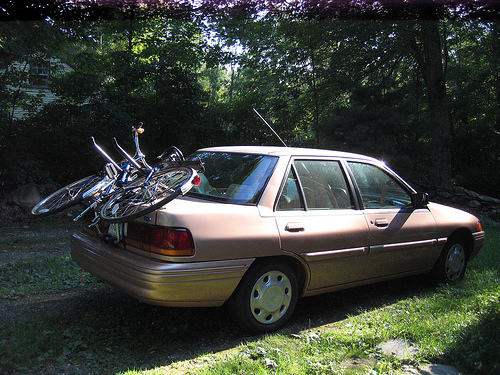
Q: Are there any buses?
A: No, there are no buses.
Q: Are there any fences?
A: No, there are no fences.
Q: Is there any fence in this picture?
A: No, there are no fences.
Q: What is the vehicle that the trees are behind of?
A: The vehicle is a car.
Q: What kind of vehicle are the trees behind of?
A: The trees are behind the car.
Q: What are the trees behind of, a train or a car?
A: The trees are behind a car.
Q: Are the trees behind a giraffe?
A: No, the trees are behind the car.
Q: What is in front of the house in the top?
A: The trees are in front of the house.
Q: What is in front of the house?
A: The trees are in front of the house.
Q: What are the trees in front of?
A: The trees are in front of the house.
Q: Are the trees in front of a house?
A: Yes, the trees are in front of a house.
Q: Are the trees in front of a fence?
A: No, the trees are in front of a house.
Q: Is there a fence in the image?
A: No, there are no fences.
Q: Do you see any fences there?
A: No, there are no fences.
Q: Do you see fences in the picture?
A: No, there are no fences.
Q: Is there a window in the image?
A: Yes, there is a window.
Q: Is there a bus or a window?
A: Yes, there is a window.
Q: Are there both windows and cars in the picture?
A: Yes, there are both a window and a car.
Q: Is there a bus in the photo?
A: No, there are no buses.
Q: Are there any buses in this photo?
A: No, there are no buses.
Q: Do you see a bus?
A: No, there are no buses.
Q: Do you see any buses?
A: No, there are no buses.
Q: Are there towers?
A: No, there are no towers.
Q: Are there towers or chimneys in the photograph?
A: No, there are no towers or chimneys.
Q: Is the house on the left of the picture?
A: Yes, the house is on the left of the image.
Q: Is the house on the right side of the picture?
A: No, the house is on the left of the image.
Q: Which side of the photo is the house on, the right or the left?
A: The house is on the left of the image.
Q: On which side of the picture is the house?
A: The house is on the left of the image.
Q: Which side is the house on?
A: The house is on the left of the image.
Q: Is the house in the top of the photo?
A: Yes, the house is in the top of the image.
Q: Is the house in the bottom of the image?
A: No, the house is in the top of the image.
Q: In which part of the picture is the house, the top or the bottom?
A: The house is in the top of the image.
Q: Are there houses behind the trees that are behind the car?
A: Yes, there is a house behind the trees.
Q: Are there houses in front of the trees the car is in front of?
A: No, the house is behind the trees.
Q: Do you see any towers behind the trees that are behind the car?
A: No, there is a house behind the trees.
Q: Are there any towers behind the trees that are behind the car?
A: No, there is a house behind the trees.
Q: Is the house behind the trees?
A: Yes, the house is behind the trees.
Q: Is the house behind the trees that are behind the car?
A: Yes, the house is behind the trees.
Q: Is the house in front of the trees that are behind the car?
A: No, the house is behind the trees.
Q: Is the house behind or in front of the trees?
A: The house is behind the trees.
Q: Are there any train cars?
A: No, there are no train cars.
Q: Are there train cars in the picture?
A: No, there are no train cars.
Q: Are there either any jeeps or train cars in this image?
A: No, there are no train cars or jeeps.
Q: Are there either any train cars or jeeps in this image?
A: No, there are no train cars or jeeps.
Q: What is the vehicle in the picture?
A: The vehicle is a car.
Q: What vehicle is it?
A: The vehicle is a car.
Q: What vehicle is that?
A: This is a car.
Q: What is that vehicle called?
A: This is a car.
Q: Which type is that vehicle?
A: This is a car.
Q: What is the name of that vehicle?
A: This is a car.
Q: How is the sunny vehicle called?
A: The vehicle is a car.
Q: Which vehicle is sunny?
A: The vehicle is a car.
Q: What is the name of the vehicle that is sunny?
A: The vehicle is a car.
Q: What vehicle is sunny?
A: The vehicle is a car.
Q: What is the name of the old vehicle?
A: The vehicle is a car.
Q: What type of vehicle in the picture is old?
A: The vehicle is a car.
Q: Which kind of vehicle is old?
A: The vehicle is a car.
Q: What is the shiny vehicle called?
A: The vehicle is a car.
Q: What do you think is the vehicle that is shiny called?
A: The vehicle is a car.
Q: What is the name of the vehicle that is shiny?
A: The vehicle is a car.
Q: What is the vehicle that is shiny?
A: The vehicle is a car.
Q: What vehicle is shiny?
A: The vehicle is a car.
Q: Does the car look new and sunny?
A: No, the car is sunny but old.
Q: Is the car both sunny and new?
A: No, the car is sunny but old.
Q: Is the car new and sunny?
A: No, the car is sunny but old.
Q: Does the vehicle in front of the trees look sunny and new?
A: No, the car is sunny but old.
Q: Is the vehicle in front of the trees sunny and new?
A: No, the car is sunny but old.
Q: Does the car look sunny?
A: Yes, the car is sunny.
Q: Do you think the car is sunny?
A: Yes, the car is sunny.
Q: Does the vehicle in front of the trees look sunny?
A: Yes, the car is sunny.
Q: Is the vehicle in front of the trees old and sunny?
A: Yes, the car is old and sunny.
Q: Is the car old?
A: Yes, the car is old.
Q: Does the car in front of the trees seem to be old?
A: Yes, the car is old.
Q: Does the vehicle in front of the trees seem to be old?
A: Yes, the car is old.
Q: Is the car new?
A: No, the car is old.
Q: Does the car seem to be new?
A: No, the car is old.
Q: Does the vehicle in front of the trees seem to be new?
A: No, the car is old.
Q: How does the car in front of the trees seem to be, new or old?
A: The car is old.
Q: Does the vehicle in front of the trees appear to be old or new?
A: The car is old.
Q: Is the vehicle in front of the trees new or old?
A: The car is old.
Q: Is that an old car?
A: Yes, that is an old car.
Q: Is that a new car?
A: No, that is an old car.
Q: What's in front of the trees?
A: The car is in front of the trees.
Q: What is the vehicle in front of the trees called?
A: The vehicle is a car.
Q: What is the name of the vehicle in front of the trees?
A: The vehicle is a car.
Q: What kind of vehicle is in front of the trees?
A: The vehicle is a car.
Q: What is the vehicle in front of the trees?
A: The vehicle is a car.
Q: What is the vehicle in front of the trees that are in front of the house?
A: The vehicle is a car.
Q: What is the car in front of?
A: The car is in front of the trees.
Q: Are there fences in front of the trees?
A: No, there is a car in front of the trees.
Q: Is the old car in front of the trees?
A: Yes, the car is in front of the trees.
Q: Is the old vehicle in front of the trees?
A: Yes, the car is in front of the trees.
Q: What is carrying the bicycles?
A: The car is carrying the bicycles.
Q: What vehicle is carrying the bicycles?
A: The vehicle is a car.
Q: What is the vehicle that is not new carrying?
A: The car is carrying bicycles.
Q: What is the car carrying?
A: The car is carrying bicycles.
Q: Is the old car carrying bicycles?
A: Yes, the car is carrying bicycles.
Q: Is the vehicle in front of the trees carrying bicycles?
A: Yes, the car is carrying bicycles.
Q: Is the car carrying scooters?
A: No, the car is carrying bicycles.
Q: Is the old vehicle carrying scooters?
A: No, the car is carrying bicycles.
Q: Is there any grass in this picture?
A: Yes, there is grass.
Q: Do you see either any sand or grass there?
A: Yes, there is grass.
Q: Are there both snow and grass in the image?
A: No, there is grass but no snow.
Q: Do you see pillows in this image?
A: No, there are no pillows.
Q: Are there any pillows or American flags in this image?
A: No, there are no pillows or American flags.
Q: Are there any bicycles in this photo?
A: Yes, there are bicycles.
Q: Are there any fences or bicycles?
A: Yes, there are bicycles.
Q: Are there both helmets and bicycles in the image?
A: No, there are bicycles but no helmets.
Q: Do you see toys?
A: No, there are no toys.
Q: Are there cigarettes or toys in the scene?
A: No, there are no toys or cigarettes.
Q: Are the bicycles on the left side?
A: Yes, the bicycles are on the left of the image.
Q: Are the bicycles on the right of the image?
A: No, the bicycles are on the left of the image.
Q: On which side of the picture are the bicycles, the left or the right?
A: The bicycles are on the left of the image.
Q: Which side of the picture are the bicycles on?
A: The bicycles are on the left of the image.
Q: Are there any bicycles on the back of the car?
A: Yes, there are bicycles on the back of the car.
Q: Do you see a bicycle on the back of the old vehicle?
A: Yes, there are bicycles on the back of the car.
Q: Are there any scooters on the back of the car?
A: No, there are bicycles on the back of the car.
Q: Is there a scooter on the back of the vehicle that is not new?
A: No, there are bicycles on the back of the car.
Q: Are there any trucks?
A: No, there are no trucks.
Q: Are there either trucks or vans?
A: No, there are no trucks or vans.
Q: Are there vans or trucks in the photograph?
A: No, there are no trucks or vans.